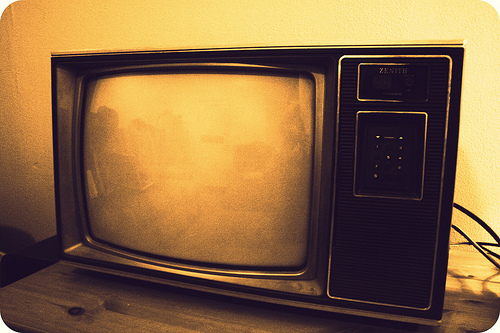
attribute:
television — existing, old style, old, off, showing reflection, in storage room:
[47, 38, 470, 333]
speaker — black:
[329, 198, 432, 306]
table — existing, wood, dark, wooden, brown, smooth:
[2, 249, 499, 333]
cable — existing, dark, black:
[453, 202, 500, 245]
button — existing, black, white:
[371, 133, 382, 151]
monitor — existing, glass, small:
[66, 61, 322, 279]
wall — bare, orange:
[0, 2, 498, 253]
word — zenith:
[376, 65, 409, 75]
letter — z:
[377, 66, 385, 74]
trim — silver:
[323, 50, 455, 314]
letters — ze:
[377, 66, 389, 75]